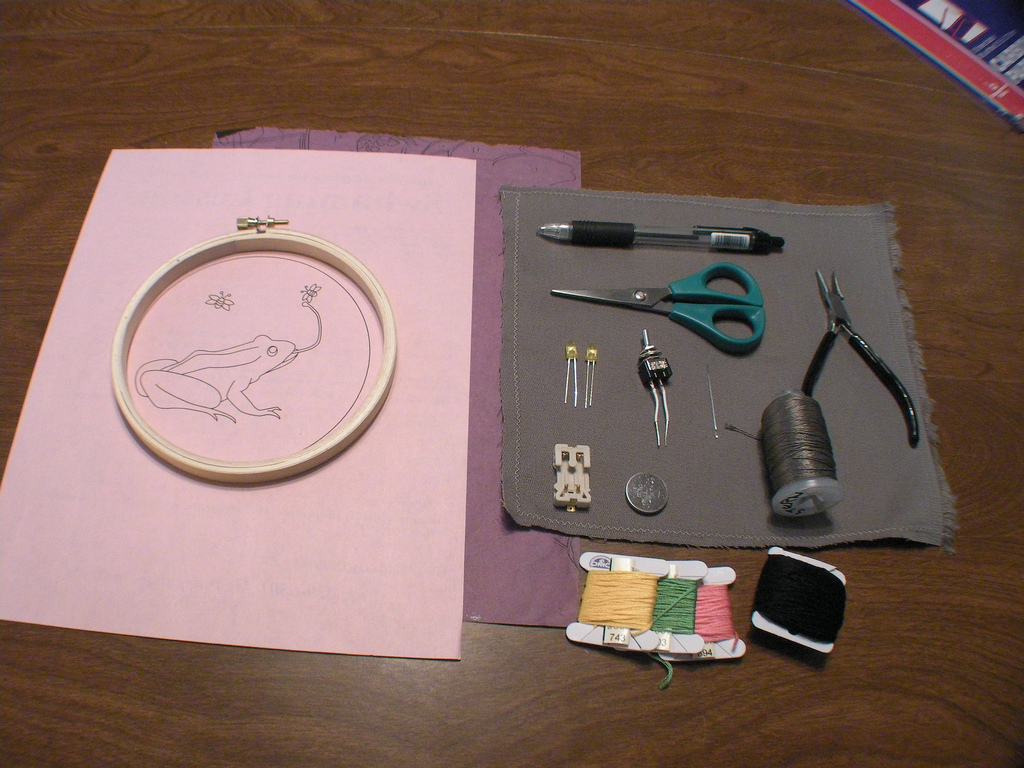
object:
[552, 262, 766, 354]
scissors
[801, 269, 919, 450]
pliers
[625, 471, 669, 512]
coin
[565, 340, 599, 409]
resistors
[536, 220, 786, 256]
pen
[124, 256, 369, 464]
drawing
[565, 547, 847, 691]
string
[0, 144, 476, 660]
paper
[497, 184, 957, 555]
cloth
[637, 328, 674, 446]
switch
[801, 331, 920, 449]
handle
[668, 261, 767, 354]
handle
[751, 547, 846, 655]
thread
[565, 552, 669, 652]
thread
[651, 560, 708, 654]
thread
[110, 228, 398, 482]
ring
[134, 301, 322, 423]
frog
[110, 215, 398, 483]
tool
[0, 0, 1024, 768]
table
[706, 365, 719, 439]
tool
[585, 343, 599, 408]
tool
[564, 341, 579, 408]
tool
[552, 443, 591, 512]
tool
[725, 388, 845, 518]
tool